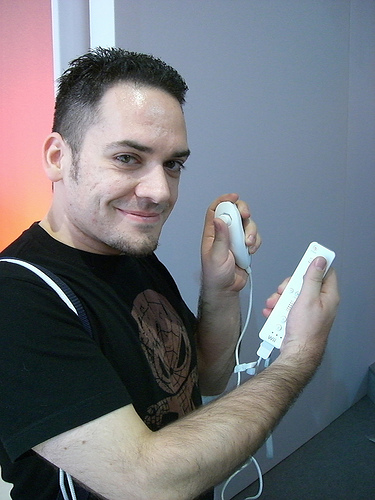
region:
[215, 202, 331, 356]
two white video game controllers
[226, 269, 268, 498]
white cord attaching controllers to each other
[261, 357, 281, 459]
gray strap hanging from controller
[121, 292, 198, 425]
design on front of black shirt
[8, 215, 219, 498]
black shirt man is wearing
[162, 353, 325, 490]
black hair on man's arm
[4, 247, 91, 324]
black strap on man's shoulder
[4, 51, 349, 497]
man holding two game controllers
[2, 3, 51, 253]
pink wall behind man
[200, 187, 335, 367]
hands holding two game controllers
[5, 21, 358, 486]
Man holding Wii controllers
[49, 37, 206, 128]
black hair on mans head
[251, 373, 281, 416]
black hair on mans arm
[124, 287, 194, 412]
Design on mans t-shirt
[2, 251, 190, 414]
black t-shirt on man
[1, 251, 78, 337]
white stripe on mans t-shirt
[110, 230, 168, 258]
black beard on mans chin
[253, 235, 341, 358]
White Wii controller in mans hand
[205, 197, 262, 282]
white Wii controller in mans hand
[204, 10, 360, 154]
White wall in background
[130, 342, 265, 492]
this is an arm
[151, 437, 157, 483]
this is an elbow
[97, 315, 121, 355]
this is a tee shirt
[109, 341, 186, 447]
the shirt is black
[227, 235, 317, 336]
this is a wii remote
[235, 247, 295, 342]
the remote is white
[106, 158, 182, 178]
these are eyes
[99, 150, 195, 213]
the eyes are brown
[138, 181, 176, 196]
this is a nose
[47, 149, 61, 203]
this is an ear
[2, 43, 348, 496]
Man holding a game controller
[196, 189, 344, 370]
White game controllers in hands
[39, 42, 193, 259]
Man has brown hair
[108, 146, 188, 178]
A pair of eyes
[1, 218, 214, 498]
A shirt is black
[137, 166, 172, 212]
Nose on a face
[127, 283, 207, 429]
Drawing on a shirt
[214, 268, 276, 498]
Wire of a controller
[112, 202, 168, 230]
Lips on man's face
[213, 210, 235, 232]
Button on a controller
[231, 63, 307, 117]
blue color on the wall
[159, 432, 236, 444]
hair on man's arm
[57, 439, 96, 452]
brown spot on man's arm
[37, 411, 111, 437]
edge of black shirt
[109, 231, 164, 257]
small beard on man's face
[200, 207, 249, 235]
small button on white remote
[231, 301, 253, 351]
white cord on remote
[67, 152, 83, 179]
tiny whiskers on side of face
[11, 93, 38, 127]
pink paint on wall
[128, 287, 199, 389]
gold symbol on man's shirt